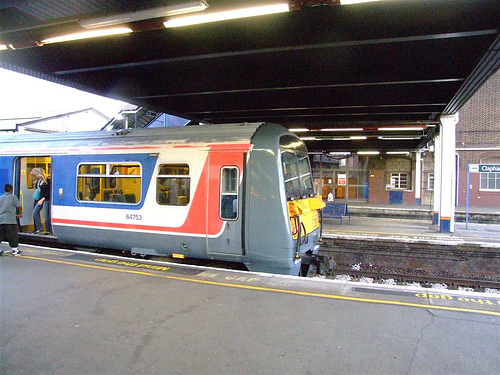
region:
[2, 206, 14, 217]
boy wearing grey shirt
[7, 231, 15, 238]
boy wearing black sweats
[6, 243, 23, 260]
boy wearing white sneakers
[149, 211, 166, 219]
white paint on train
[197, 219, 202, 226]
red paint on train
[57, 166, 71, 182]
blue paint on train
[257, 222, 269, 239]
grey paint on train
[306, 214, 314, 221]
yellow paint on train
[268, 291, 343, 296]
yellow stripe on platform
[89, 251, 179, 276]
yellow lettering on platform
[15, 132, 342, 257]
large multi colored train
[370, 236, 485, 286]
train tracks near a station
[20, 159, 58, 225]
woman getting off a train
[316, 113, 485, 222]
large train station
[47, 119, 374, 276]
red stripe on a train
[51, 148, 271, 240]
red blue and white on a train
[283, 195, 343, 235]
yellow bumper on a train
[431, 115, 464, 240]
white posts at a train station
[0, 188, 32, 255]
person in dark clothing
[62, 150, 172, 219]
window on a train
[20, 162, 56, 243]
People getting off the train.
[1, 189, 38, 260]
A person on the platform.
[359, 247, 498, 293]
Tracks on the ground.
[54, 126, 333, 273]
A train on the tracks.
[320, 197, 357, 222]
Blue bench on the platform.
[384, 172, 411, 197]
Windown on the building.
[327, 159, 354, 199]
Door to the building.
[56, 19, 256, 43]
Lights on the ceiling of the platform.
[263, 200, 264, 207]
part of a train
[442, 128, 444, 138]
part of a building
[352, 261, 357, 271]
part of a rail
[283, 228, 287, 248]
part of a train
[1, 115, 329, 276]
Train on the tracks.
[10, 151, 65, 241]
door in the train.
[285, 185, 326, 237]
Yellow color on the front of the train.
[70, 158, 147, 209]
Window on the train.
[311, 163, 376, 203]
Door in the building.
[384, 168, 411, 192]
Window in the building.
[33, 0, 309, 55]
lights in the ceiling.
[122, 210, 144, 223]
Blue numbers on the train.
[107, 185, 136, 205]
Seats on the train.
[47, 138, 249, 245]
Red white and blue coloring.